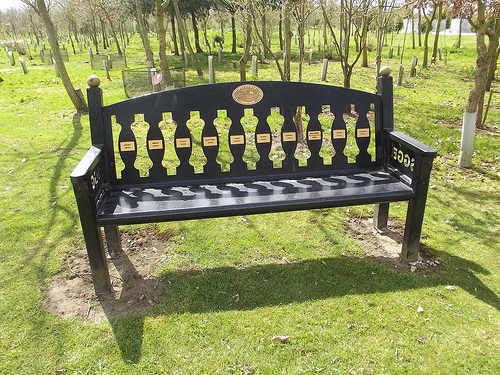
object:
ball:
[86, 73, 101, 87]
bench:
[68, 68, 440, 294]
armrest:
[69, 144, 105, 184]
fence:
[397, 17, 475, 35]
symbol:
[232, 83, 264, 105]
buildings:
[446, 17, 474, 35]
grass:
[0, 31, 498, 374]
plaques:
[354, 104, 371, 164]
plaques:
[329, 107, 347, 167]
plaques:
[306, 105, 324, 167]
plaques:
[224, 109, 249, 173]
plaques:
[253, 107, 273, 169]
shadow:
[91, 237, 499, 365]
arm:
[69, 144, 105, 186]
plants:
[462, 0, 498, 168]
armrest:
[386, 131, 438, 158]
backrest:
[101, 80, 381, 186]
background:
[1, 2, 498, 80]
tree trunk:
[35, 0, 87, 112]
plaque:
[115, 114, 141, 179]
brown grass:
[447, 167, 476, 183]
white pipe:
[457, 110, 479, 169]